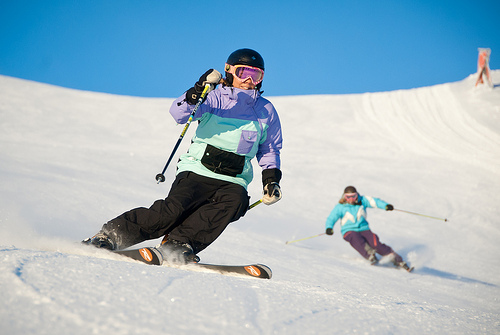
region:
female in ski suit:
[80, 45, 285, 282]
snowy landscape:
[3, 1, 498, 333]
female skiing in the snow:
[84, 48, 282, 296]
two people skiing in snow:
[83, 46, 448, 276]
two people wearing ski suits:
[83, 48, 450, 280]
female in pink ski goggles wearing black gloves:
[81, 46, 283, 292]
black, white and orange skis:
[117, 245, 273, 278]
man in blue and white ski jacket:
[323, 183, 416, 272]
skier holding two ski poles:
[287, 185, 449, 276]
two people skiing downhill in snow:
[83, 48, 445, 281]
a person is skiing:
[85, 45, 286, 285]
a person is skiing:
[315, 180, 453, 275]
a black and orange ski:
[112, 245, 160, 266]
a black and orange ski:
[194, 261, 271, 278]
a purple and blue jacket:
[174, 78, 280, 191]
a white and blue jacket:
[325, 197, 385, 233]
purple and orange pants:
[344, 230, 399, 260]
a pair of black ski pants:
[99, 172, 246, 252]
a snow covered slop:
[0, 69, 499, 333]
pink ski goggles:
[219, 61, 265, 82]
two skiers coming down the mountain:
[72, 21, 436, 273]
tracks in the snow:
[21, 223, 331, 334]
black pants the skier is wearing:
[105, 175, 251, 258]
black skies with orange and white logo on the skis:
[120, 241, 274, 281]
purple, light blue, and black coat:
[179, 87, 277, 190]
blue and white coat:
[325, 195, 387, 230]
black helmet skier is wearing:
[227, 45, 260, 81]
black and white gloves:
[182, 69, 281, 207]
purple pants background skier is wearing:
[347, 227, 409, 272]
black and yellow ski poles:
[147, 79, 275, 214]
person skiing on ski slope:
[160, 41, 267, 281]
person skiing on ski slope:
[341, 181, 388, 251]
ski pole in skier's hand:
[166, 98, 195, 169]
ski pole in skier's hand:
[250, 184, 264, 211]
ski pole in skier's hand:
[277, 222, 327, 247]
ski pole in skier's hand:
[380, 199, 460, 236]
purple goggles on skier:
[232, 56, 271, 93]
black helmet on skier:
[228, 48, 262, 78]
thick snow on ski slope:
[49, 248, 276, 334]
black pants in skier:
[121, 170, 258, 260]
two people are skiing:
[80, 21, 470, 325]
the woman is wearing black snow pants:
[67, 176, 287, 316]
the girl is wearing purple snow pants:
[325, 210, 433, 287]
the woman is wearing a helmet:
[202, 40, 270, 97]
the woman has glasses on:
[210, 25, 280, 125]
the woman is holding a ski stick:
[135, 6, 290, 223]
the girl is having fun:
[307, 147, 474, 311]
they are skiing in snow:
[61, 44, 454, 309]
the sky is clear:
[301, 0, 396, 72]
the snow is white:
[15, 137, 79, 330]